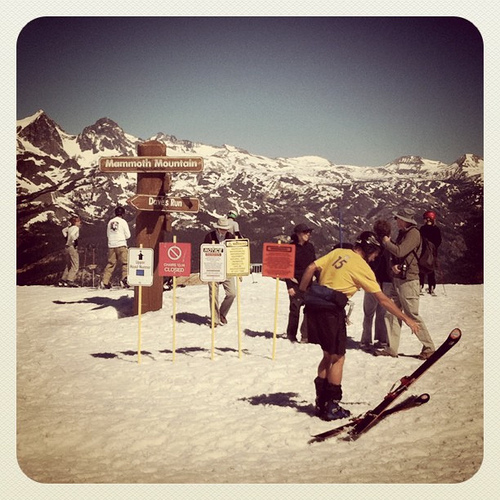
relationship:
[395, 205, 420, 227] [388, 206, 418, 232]
hat on head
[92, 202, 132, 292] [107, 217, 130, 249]
man wearing t-shirt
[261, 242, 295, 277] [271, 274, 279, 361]
banner on pole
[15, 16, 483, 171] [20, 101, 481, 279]
sky over mountain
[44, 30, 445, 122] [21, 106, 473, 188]
sky over mountains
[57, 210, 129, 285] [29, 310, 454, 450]
people on top of snow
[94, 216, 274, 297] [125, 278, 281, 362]
signs on poles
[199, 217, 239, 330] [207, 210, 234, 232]
person in hat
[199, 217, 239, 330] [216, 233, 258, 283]
person walking towards sign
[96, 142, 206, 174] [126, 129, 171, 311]
destination signs on brown column